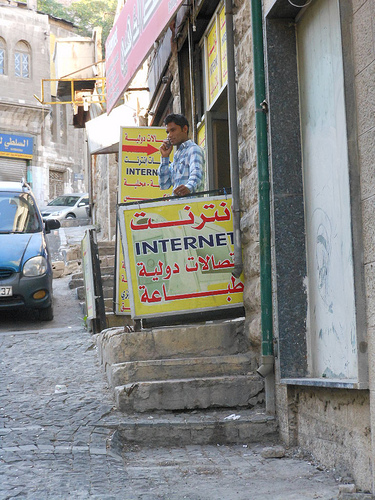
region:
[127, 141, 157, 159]
the arrow points right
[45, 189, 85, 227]
the car is gray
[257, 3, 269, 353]
the pipe is green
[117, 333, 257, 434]
there are four steps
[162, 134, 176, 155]
the man is on the phone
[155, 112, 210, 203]
man on a cell phone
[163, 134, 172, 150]
grey cell phone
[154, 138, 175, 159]
right hand holding a phone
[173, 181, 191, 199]
left hand on a sign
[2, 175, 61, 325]
grey car in the alley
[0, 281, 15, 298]
license plate of the grey car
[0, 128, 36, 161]
blue and yellow sign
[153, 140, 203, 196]
long sleeved shirt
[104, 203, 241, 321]
A yellow sign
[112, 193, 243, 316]
A sign that says internet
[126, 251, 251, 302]
The red foreign language writing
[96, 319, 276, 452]
The concrete stairs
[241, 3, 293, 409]
The green pipe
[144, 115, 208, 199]
The man in the plaid shirt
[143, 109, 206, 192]
The man is talking on the phone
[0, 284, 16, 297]
The partial plate of the car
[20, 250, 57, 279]
The front headlight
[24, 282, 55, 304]
The little yellow light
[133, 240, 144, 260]
a letter is written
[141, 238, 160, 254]
a letter is written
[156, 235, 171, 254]
a letter is written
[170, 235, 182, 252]
a letter is written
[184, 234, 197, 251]
a letter is written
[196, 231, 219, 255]
a letter is written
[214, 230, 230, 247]
a letter is written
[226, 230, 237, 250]
a letter is written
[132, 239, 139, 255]
a letter is written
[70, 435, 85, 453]
a brick on the road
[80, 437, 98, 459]
a brick on the road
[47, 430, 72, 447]
a brick on the road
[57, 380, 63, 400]
a brick on the road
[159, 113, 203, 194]
the man is standing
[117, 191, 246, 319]
the sign is multi colored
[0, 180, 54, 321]
the car is parked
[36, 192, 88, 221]
the car is silver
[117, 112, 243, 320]
the man has his hand on the sign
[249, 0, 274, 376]
the drain pipe is green and gray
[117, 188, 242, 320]
A store sign on the ground.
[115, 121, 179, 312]
a tall sign next to the man.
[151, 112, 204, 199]
A man talking on a cellphone.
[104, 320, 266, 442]
Stone stairs by the store.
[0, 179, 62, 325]
A car on the narrow street.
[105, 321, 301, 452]
the stairs are uneven.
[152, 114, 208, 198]
The man in the plaid shirt is on the phone.